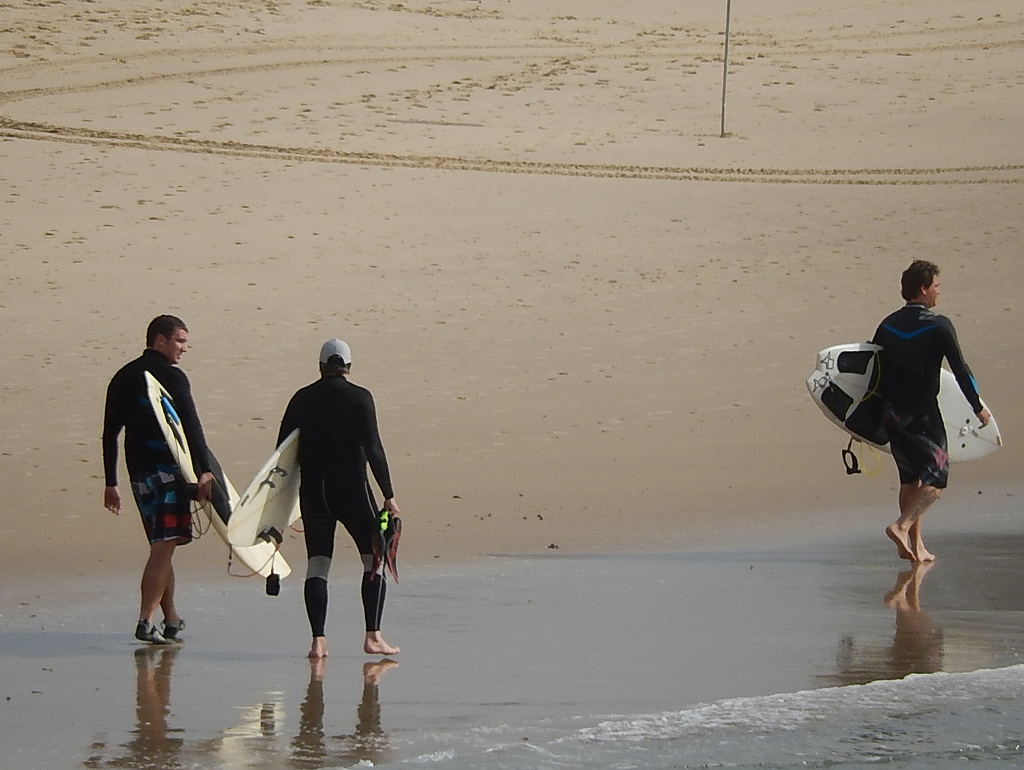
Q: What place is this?
A: It is a shore.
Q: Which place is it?
A: It is a shore.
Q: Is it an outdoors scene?
A: Yes, it is outdoors.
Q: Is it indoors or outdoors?
A: It is outdoors.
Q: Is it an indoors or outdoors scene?
A: It is outdoors.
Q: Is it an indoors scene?
A: No, it is outdoors.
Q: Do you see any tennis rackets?
A: No, there are no tennis rackets.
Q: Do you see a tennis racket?
A: No, there are no rackets.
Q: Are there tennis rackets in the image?
A: No, there are no tennis rackets.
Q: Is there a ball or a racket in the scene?
A: No, there are no rackets or balls.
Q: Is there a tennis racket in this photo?
A: No, there are no rackets.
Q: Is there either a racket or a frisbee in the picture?
A: No, there are no rackets or frisbees.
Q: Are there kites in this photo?
A: No, there are no kites.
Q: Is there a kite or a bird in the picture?
A: No, there are no kites or birds.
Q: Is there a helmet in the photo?
A: No, there are no helmets.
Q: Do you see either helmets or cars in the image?
A: No, there are no helmets or cars.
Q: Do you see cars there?
A: No, there are no cars.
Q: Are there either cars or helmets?
A: No, there are no cars or helmets.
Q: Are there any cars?
A: No, there are no cars.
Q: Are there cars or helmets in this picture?
A: No, there are no cars or helmets.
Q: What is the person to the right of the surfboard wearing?
A: The person is wearing shorts.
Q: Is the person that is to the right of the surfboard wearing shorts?
A: Yes, the person is wearing shorts.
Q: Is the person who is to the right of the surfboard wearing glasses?
A: No, the person is wearing shorts.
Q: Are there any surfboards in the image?
A: Yes, there is a surfboard.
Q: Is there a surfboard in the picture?
A: Yes, there is a surfboard.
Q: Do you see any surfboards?
A: Yes, there is a surfboard.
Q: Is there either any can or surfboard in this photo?
A: Yes, there is a surfboard.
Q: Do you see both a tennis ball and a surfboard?
A: No, there is a surfboard but no tennis balls.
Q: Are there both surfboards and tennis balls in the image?
A: No, there is a surfboard but no tennis balls.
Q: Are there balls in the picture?
A: No, there are no balls.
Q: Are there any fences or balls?
A: No, there are no balls or fences.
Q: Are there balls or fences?
A: No, there are no balls or fences.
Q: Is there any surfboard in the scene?
A: Yes, there is a surfboard.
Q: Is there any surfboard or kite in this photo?
A: Yes, there is a surfboard.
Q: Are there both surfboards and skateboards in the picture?
A: No, there is a surfboard but no skateboards.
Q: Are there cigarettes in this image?
A: No, there are no cigarettes.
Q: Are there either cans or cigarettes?
A: No, there are no cigarettes or cans.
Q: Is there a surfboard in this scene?
A: Yes, there is a surfboard.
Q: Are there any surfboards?
A: Yes, there is a surfboard.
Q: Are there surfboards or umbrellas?
A: Yes, there is a surfboard.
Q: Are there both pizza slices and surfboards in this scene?
A: No, there is a surfboard but no pizza slices.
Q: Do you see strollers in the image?
A: No, there are no strollers.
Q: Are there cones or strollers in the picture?
A: No, there are no strollers or cones.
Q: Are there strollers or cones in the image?
A: No, there are no strollers or cones.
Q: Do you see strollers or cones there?
A: No, there are no strollers or cones.